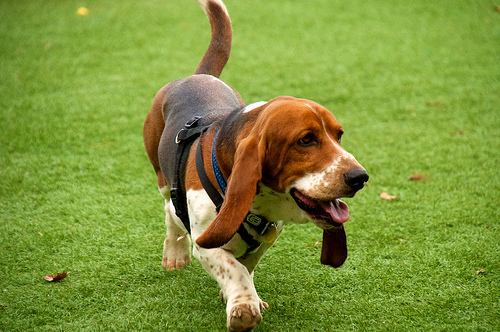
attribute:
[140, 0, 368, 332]
dog — brown, beagle, small, white, walking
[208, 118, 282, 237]
collar — blue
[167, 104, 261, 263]
harness — black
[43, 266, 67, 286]
leaf — brown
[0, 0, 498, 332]
grass — green, field, thick, short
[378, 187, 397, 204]
leaf — brown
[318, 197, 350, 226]
tongue — pink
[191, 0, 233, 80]
tail — brown, sticking up, white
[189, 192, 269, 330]
front leg — white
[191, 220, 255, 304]
speckles — brown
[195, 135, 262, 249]
ear — brown, long, floppy, hanging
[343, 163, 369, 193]
nose — black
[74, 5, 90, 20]
ball — yellow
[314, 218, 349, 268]
ear — brown, floppy, long, hanging